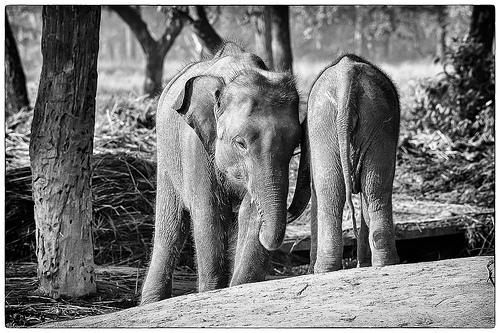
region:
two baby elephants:
[122, 37, 419, 307]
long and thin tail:
[333, 70, 365, 260]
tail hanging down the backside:
[328, 91, 360, 254]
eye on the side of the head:
[231, 136, 245, 157]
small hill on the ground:
[86, 253, 494, 328]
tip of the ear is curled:
[171, 79, 201, 113]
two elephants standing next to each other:
[130, 42, 427, 311]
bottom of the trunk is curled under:
[245, 155, 285, 258]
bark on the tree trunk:
[23, 5, 126, 300]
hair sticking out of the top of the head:
[223, 58, 300, 107]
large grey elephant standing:
[141, 37, 302, 314]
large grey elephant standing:
[293, 49, 407, 276]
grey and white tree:
[22, 2, 110, 301]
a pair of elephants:
[127, 43, 411, 299]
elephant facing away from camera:
[296, 37, 411, 275]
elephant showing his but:
[298, 37, 400, 276]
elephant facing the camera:
[141, 34, 298, 293]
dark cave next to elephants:
[398, 232, 479, 264]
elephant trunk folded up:
[246, 172, 298, 258]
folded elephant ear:
[170, 68, 221, 150]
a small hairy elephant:
[143, 52, 308, 284]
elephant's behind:
[294, 81, 391, 224]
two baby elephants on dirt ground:
[130, 32, 422, 310]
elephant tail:
[324, 93, 391, 267]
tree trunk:
[22, 4, 102, 304]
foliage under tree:
[392, 41, 492, 213]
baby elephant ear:
[165, 70, 228, 165]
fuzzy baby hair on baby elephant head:
[230, 62, 307, 109]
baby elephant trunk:
[243, 173, 297, 262]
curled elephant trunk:
[235, 178, 295, 250]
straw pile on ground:
[8, 122, 157, 320]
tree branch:
[111, 8, 160, 50]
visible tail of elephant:
[337, 85, 357, 230]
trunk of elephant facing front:
[256, 181, 283, 246]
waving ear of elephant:
[176, 75, 213, 147]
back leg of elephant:
[315, 175, 345, 270]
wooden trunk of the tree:
[30, 10, 100, 285]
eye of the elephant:
[230, 130, 245, 145]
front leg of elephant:
[185, 205, 225, 285]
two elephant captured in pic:
[135, 40, 395, 280]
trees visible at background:
[130, 5, 375, 45]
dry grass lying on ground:
[95, 150, 146, 250]